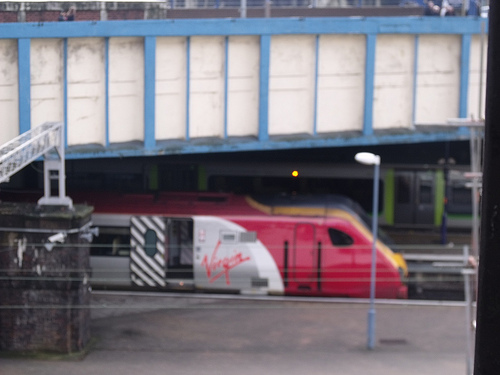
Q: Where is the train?
A: On the tracks.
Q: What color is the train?
A: Red and white.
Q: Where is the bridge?
A: Above the train.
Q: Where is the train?
A: The train station.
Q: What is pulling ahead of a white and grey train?
A: A red, orange and blue train.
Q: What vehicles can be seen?
A: Two trains on a track.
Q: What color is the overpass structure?
A: The overpass structure is blue and white.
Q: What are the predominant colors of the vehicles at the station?
A: Red and grey are the colors of the trains, passing the station.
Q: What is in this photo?
A: Two trains underneath a bridge.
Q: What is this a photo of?
A: Train.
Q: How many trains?
A: 2.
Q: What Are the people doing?
A: Standing on the bridge.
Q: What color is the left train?
A: Red.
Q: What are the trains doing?
A: Moving.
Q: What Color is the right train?
A: Black and white.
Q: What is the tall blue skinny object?
A: Light pole.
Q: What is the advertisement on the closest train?
A: Virgin.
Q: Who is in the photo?
A: Nobody.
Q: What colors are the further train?
A: Green and silver.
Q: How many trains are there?
A: Two.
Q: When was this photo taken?
A: Daytime.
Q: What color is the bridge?
A: White and blue.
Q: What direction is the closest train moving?
A: Right.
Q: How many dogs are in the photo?
A: Zero.